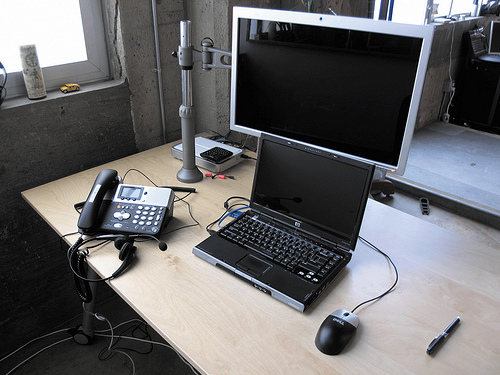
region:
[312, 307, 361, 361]
computer mouse on the desk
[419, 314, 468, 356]
pen on the desk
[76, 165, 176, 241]
phone on the desk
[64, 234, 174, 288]
headset on the desk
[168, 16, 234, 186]
tv holder on the desk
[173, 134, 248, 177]
box with cord on the desk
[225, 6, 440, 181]
tv mounted to the desk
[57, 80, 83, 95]
yellow car in the window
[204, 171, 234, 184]
red things on the desk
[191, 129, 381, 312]
laptop on the desk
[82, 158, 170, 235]
that is a telephone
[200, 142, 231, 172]
that is a calculator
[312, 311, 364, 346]
the mouse of a computer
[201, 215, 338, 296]
this is a key board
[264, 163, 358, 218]
this is the monitor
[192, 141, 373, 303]
this is a lap top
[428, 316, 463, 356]
this is a pen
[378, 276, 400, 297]
this is a cable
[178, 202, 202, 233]
this is a cable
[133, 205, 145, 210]
silver button on phone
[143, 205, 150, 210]
silver button on phone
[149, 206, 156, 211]
silver button on phone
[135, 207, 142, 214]
silver button on phone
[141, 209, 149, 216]
silver button on phone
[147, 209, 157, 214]
silver button on phone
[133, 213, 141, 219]
silver button on phone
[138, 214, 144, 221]
silver button on phone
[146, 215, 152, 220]
silver button on phone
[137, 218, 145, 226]
silver button on phone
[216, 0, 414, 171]
monitor of the computer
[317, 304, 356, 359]
computer mouse on desk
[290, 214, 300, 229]
brand logo of laptop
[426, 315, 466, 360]
pen on the desk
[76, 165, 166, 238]
phone on the desk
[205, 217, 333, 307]
keyboard of the laptop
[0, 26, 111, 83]
window in the corner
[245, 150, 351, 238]
screen of the laptop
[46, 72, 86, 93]
car on the shelf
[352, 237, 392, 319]
cord of the mouse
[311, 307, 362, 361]
A computer mouse.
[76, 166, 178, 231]
A landline phone on a desk.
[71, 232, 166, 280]
Call center head phones.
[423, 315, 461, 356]
A stylus pen sitting on the desk.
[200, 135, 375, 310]
A laptop sitting on the desk.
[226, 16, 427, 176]
A computer monitor.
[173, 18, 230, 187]
A computer monitor stand.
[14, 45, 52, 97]
A candle on the window sill.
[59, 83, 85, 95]
A matchbox car.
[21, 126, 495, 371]
A wooden desk.